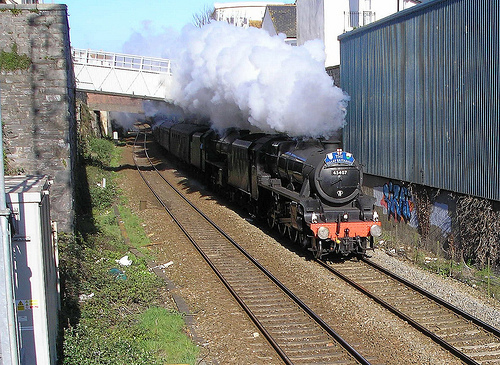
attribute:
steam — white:
[140, 28, 353, 139]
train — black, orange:
[153, 112, 375, 245]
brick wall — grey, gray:
[3, 5, 75, 229]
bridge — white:
[71, 52, 185, 100]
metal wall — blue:
[333, 20, 499, 188]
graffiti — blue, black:
[379, 179, 423, 221]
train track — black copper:
[132, 135, 494, 363]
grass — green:
[78, 138, 172, 361]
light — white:
[318, 227, 329, 238]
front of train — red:
[312, 223, 382, 237]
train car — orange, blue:
[311, 151, 382, 257]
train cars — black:
[148, 124, 324, 206]